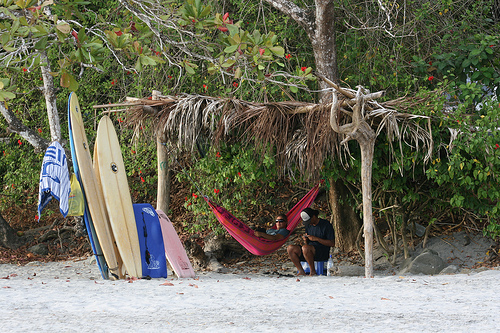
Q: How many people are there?
A: One.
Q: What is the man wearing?
A: Hat.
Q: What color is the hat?
A: Navy and white.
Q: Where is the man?
A: An island.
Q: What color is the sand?
A: White.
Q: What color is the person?
A: Black.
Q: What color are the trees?
A: Green.